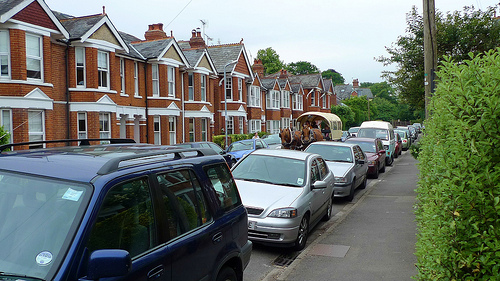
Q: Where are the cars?
A: Lining the road.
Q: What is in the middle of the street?
A: Horse drawn buggy.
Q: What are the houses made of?
A: Brick.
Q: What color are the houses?
A: Orange.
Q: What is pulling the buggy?
A: Horses.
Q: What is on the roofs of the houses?
A: Chimneys.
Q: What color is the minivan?
A: Blue.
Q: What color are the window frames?
A: White.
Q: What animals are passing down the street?
A: Horses.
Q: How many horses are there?
A: Two.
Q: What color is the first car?
A: Blue.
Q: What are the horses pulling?
A: A carriage.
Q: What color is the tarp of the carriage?
A: Beige.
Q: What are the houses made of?
A: Brick.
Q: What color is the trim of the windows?
A: White.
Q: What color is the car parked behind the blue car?
A: Silver.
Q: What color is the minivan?
A: White and teal.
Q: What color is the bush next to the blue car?
A: Green.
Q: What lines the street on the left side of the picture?
A: Red brick houses.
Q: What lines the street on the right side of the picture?
A: Automobiles.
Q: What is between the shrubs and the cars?
A: Sidewalk.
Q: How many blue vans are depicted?
A: One.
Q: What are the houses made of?
A: Brick.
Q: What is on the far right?
A: Hedge.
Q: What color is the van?
A: Blue.